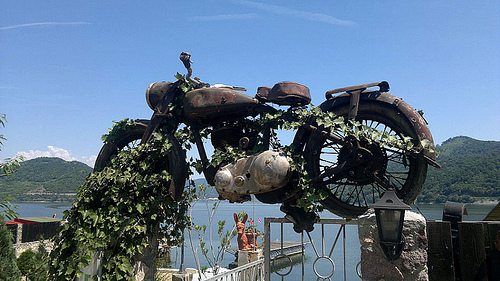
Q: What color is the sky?
A: Blue.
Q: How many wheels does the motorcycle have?
A: 2.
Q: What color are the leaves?
A: Green.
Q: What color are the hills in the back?
A: Green.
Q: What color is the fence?
A: White.